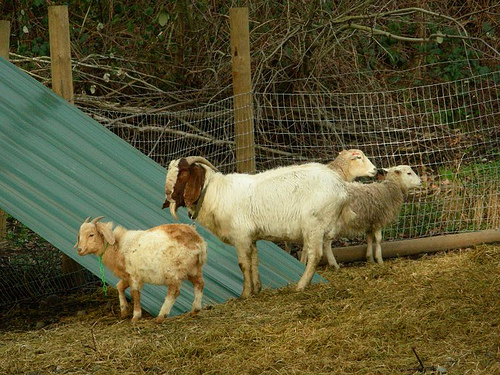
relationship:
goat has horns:
[162, 152, 356, 297] [187, 152, 217, 171]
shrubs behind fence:
[3, 1, 500, 65] [6, 73, 500, 309]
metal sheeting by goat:
[1, 61, 333, 316] [161, 156, 357, 298]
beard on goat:
[170, 197, 179, 218] [162, 152, 356, 297]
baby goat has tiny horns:
[73, 217, 208, 322] [82, 215, 103, 224]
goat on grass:
[162, 152, 356, 297] [3, 255, 498, 373]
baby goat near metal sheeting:
[73, 217, 208, 322] [1, 61, 333, 316]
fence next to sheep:
[6, 73, 500, 309] [286, 150, 428, 270]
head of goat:
[161, 152, 220, 214] [162, 152, 356, 297]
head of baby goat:
[74, 216, 117, 257] [73, 217, 208, 322]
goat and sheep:
[161, 156, 357, 298] [286, 150, 428, 270]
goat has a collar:
[162, 152, 356, 297] [190, 175, 209, 221]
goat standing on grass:
[162, 152, 356, 297] [3, 255, 498, 373]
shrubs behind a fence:
[3, 1, 500, 65] [6, 73, 500, 309]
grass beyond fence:
[372, 155, 499, 239] [6, 73, 500, 309]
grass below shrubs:
[372, 155, 499, 239] [3, 1, 500, 65]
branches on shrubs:
[23, 50, 310, 157] [3, 1, 500, 65]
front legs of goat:
[237, 236, 262, 300] [162, 152, 356, 297]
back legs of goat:
[293, 233, 328, 291] [162, 152, 356, 297]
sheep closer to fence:
[286, 150, 428, 270] [6, 73, 500, 309]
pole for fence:
[230, 3, 257, 171] [6, 73, 500, 309]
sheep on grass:
[286, 150, 428, 270] [3, 255, 498, 373]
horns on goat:
[187, 152, 217, 171] [162, 152, 356, 297]